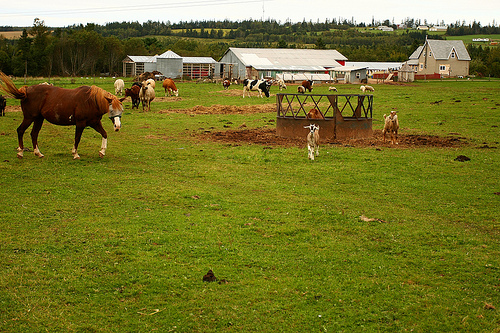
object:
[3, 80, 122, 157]
brown horse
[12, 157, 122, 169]
grass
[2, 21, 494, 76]
green trees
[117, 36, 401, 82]
barn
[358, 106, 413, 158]
animal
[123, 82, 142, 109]
animal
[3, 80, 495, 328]
field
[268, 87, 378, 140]
pen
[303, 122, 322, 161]
goat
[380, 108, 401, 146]
goat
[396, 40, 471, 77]
house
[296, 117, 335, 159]
animal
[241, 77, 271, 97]
animal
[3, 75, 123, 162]
animal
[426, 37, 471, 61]
roof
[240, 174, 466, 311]
grass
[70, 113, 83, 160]
legs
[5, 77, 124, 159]
horse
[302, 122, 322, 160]
goats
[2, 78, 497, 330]
grass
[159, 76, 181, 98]
animal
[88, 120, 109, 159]
leg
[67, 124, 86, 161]
leg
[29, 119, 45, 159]
leg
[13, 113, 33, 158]
leg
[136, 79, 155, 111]
animal